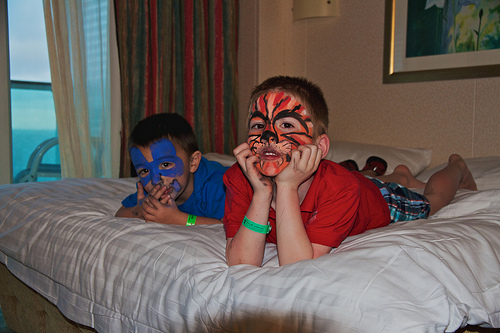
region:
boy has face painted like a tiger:
[241, 88, 318, 184]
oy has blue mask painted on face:
[110, 105, 198, 250]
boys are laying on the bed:
[91, 88, 377, 278]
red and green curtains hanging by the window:
[98, 7, 254, 195]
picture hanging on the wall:
[365, 8, 495, 87]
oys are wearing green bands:
[168, 208, 281, 257]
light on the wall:
[281, 0, 362, 36]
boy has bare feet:
[396, 139, 493, 208]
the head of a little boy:
[198, 69, 328, 179]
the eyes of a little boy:
[244, 111, 308, 131]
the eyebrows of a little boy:
[242, 101, 313, 125]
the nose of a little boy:
[255, 132, 285, 142]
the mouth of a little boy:
[260, 138, 282, 162]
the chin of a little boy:
[258, 166, 282, 187]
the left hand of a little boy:
[270, 146, 327, 194]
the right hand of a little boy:
[228, 133, 270, 193]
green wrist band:
[241, 214, 271, 235]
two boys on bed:
[112, 74, 465, 252]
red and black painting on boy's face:
[237, 77, 324, 179]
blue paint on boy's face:
[122, 116, 198, 200]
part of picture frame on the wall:
[384, 0, 495, 85]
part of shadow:
[189, 309, 333, 331]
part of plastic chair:
[15, 132, 52, 186]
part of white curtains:
[45, 0, 115, 174]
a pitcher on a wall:
[359, 0, 496, 102]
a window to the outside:
[1, 0, 121, 174]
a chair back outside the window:
[16, 125, 103, 178]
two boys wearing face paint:
[86, 81, 343, 200]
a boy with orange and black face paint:
[238, 72, 330, 179]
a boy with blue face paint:
[117, 114, 198, 205]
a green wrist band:
[239, 202, 272, 247]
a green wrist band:
[181, 203, 207, 240]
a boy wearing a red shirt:
[216, 70, 388, 261]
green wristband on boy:
[240, 216, 272, 237]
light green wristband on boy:
[183, 210, 200, 228]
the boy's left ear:
[190, 148, 202, 172]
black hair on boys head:
[137, 109, 197, 147]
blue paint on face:
[122, 140, 191, 176]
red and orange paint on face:
[243, 88, 313, 175]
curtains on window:
[47, 4, 235, 158]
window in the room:
[9, 4, 60, 180]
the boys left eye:
[280, 123, 295, 133]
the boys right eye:
[248, 119, 265, 132]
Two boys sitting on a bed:
[5, 76, 495, 327]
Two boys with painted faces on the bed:
[4, 71, 496, 325]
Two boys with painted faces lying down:
[113, 68, 478, 263]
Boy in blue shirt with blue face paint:
[116, 108, 227, 230]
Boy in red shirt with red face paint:
[218, 75, 474, 271]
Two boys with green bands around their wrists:
[110, 70, 488, 264]